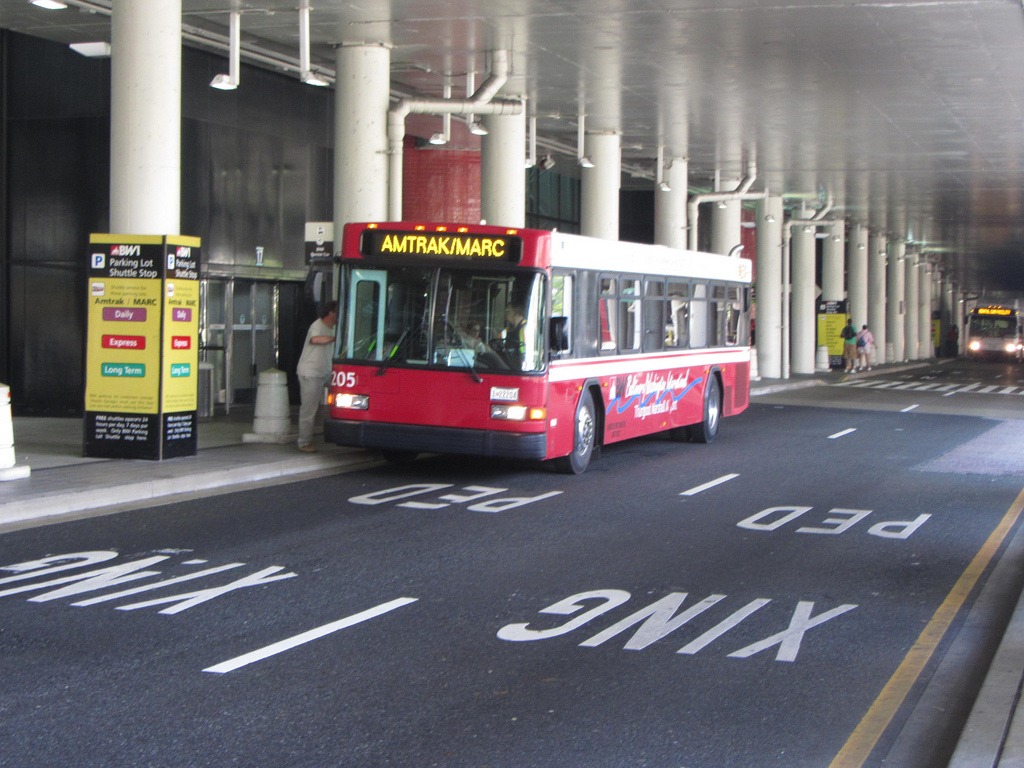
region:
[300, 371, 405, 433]
the headlight on a bus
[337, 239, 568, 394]
the windshield on a bus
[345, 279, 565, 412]
windshield wipers on a bus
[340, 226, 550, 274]
letters on top of a bus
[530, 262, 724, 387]
side windows on a bus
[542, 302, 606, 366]
side mirror on a bus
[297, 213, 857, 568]
a bus on the road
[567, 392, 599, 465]
the round rubber tire of the bus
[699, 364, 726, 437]
the round rubber tire of the bus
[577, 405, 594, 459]
the silver hubcap of the bus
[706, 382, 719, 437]
the silver hubcap of the bus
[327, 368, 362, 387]
the white number 205 on the bus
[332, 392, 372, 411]
the bright headlight of the bus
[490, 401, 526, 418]
the bright headlight of the bus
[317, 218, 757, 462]
the red and white bus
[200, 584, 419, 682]
the white line on the street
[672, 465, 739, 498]
the white line on the street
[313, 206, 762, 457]
A red and white bus is traveling down the road.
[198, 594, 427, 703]
A white line is painted on the road.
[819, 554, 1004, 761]
A yellow line is painted on the road.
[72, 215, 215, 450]
A large sign is on the ground in front of the business.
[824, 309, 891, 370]
Some people are walking on the sidewalk.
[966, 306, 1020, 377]
Another bus is traveling down the road.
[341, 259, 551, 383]
A large windshield infront of the bus.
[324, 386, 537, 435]
Two headlights infront of the bus.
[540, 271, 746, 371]
A row of windows on the side of the bus.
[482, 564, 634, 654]
A letter on the road.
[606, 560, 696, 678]
A letter on the road.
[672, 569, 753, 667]
A letter on the road.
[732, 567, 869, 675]
A letter on the road.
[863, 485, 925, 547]
A letter on the road.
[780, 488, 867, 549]
A letter on the road.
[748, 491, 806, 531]
A letter on the road.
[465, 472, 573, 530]
A letter on the road.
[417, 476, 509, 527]
A letter on the road.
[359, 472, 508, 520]
A letter on the road.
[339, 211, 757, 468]
A red and white bus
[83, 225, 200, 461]
A large sign around a column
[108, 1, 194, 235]
A white column with a sign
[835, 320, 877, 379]
People on a sidewalk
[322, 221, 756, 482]
red and white bus on the street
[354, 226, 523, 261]
black sign with yellow letters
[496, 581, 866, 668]
white letters painted on the roadway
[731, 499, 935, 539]
white letters painted on the roadway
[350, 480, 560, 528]
white letters painted on the roadway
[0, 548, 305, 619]
white letters painted on the roadway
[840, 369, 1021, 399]
white lines painted as a crosswalk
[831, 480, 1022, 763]
yellow lines painted on side of roadway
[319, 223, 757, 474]
large red and white public bus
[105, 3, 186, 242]
large white cement pillar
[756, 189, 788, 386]
large white cement pillar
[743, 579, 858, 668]
A letter on the road.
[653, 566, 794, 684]
A letter on the road.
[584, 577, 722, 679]
A letter on the road.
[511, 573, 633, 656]
A letter on the road.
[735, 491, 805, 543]
A letter on the road.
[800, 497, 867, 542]
A letter on the road.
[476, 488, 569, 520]
A letter on the road.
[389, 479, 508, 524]
A letter on the road.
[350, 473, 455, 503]
A letter on the road.